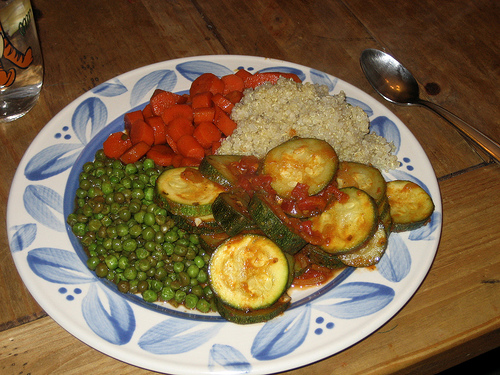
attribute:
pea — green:
[168, 227, 178, 242]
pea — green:
[136, 212, 146, 222]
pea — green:
[143, 188, 157, 202]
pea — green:
[88, 219, 100, 231]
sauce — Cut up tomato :
[235, 173, 312, 219]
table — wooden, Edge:
[4, 0, 484, 366]